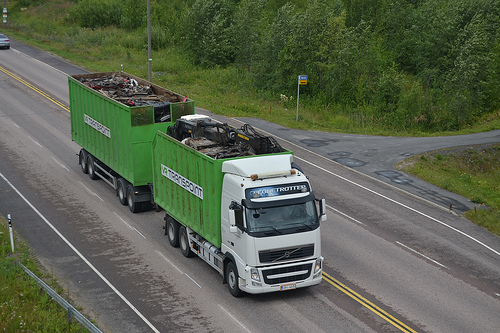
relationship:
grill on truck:
[265, 243, 307, 267] [141, 136, 334, 304]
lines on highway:
[339, 253, 371, 312] [0, 32, 500, 332]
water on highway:
[48, 204, 107, 242] [0, 32, 500, 332]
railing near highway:
[55, 298, 73, 314] [0, 32, 500, 332]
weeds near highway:
[36, 259, 49, 274] [0, 32, 500, 332]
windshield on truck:
[261, 205, 319, 232] [141, 136, 334, 304]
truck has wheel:
[141, 136, 334, 304] [163, 211, 196, 256]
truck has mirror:
[141, 136, 334, 304] [318, 188, 333, 223]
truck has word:
[141, 136, 334, 304] [161, 163, 194, 193]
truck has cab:
[141, 136, 334, 304] [229, 183, 312, 224]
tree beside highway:
[327, 12, 418, 103] [349, 180, 455, 304]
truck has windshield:
[141, 136, 334, 304] [261, 205, 319, 232]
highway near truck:
[349, 180, 455, 304] [141, 136, 334, 304]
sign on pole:
[295, 70, 315, 88] [288, 91, 310, 111]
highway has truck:
[0, 32, 500, 332] [141, 136, 334, 304]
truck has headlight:
[141, 136, 334, 304] [241, 257, 267, 284]